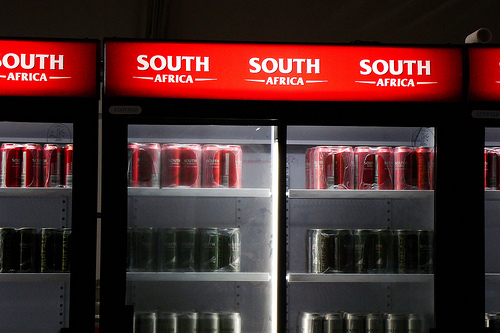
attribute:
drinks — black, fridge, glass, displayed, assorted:
[126, 133, 433, 328]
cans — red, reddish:
[130, 139, 434, 188]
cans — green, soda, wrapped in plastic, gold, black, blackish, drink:
[127, 223, 429, 278]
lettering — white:
[134, 54, 441, 91]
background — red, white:
[102, 37, 472, 104]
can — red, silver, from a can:
[219, 140, 246, 188]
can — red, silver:
[179, 144, 201, 189]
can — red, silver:
[200, 140, 223, 190]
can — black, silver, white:
[219, 309, 242, 333]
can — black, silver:
[178, 309, 198, 333]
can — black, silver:
[298, 306, 323, 333]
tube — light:
[267, 122, 281, 329]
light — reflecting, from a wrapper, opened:
[132, 136, 248, 187]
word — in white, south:
[249, 55, 321, 77]